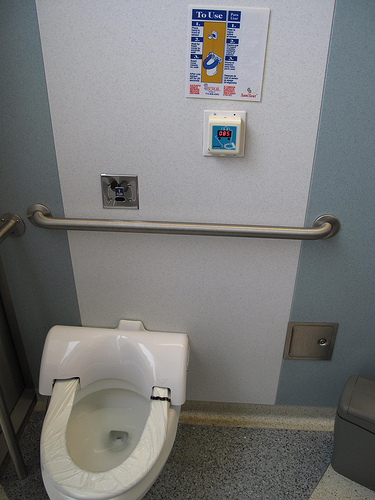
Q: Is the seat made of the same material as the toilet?
A: Yes, both the seat and the toilet are made of plastic.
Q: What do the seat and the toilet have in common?
A: The material, both the seat and the toilet are plastic.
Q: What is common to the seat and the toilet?
A: The material, both the seat and the toilet are plastic.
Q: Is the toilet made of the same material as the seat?
A: Yes, both the toilet and the seat are made of plastic.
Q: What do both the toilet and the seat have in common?
A: The material, both the toilet and the seat are plastic.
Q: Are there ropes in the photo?
A: No, there are no ropes.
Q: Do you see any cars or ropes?
A: No, there are no ropes or cars.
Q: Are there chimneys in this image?
A: No, there are no chimneys.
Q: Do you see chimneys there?
A: No, there are no chimneys.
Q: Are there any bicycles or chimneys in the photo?
A: No, there are no chimneys or bicycles.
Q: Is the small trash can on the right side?
A: Yes, the trash bin is on the right of the image.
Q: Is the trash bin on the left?
A: No, the trash bin is on the right of the image.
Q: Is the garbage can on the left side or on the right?
A: The garbage can is on the right of the image.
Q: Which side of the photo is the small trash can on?
A: The garbage can is on the right of the image.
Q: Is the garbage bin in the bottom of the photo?
A: Yes, the garbage bin is in the bottom of the image.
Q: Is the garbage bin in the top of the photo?
A: No, the garbage bin is in the bottom of the image.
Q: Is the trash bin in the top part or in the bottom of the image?
A: The trash bin is in the bottom of the image.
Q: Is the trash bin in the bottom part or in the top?
A: The trash bin is in the bottom of the image.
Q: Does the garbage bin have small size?
A: Yes, the garbage bin is small.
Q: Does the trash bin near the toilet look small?
A: Yes, the trash bin is small.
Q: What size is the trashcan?
A: The trashcan is small.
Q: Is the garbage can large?
A: No, the garbage can is small.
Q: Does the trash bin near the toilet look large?
A: No, the trash can is small.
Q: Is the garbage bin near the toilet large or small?
A: The garbage can is small.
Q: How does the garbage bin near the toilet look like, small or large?
A: The garbage can is small.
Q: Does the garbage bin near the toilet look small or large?
A: The garbage can is small.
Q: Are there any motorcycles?
A: No, there are no motorcycles.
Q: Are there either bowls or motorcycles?
A: No, there are no motorcycles or bowls.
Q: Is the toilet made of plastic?
A: Yes, the toilet is made of plastic.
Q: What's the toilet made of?
A: The toilet is made of plastic.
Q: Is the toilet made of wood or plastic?
A: The toilet is made of plastic.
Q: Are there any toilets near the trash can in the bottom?
A: Yes, there is a toilet near the trash bin.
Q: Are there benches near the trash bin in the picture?
A: No, there is a toilet near the trash bin.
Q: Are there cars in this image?
A: No, there are no cars.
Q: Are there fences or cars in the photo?
A: No, there are no cars or fences.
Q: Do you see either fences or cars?
A: No, there are no cars or fences.